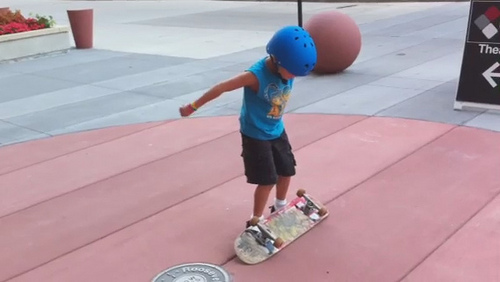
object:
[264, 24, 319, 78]
helmet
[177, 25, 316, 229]
boy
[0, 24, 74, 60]
bed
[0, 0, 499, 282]
outdoors scene